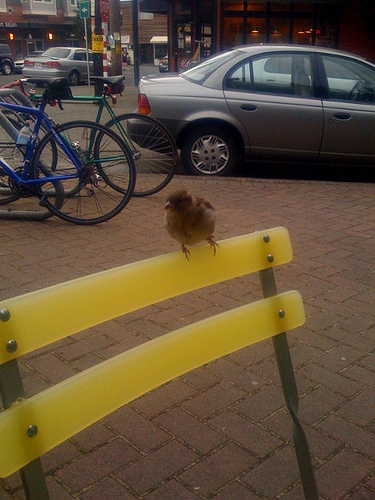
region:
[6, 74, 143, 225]
bright blue parked on sidewalk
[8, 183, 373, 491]
red brick sidewalk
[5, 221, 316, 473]
yellow slats of chair on sidewalk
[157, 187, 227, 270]
small brown bird perched on chair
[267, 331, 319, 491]
black iron twisted back of chair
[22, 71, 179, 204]
bright green bike parked on sidewalk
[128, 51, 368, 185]
silver car parked on street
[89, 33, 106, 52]
yellow on black pole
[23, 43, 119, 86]
silver car parked on street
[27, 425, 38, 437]
silver bolt in yellow chair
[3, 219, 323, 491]
yellow chair with bird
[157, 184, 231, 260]
small brown bird sitting on yellow chair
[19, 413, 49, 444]
silver screw in yellow chair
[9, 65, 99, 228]
blue collapsing bike parked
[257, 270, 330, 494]
twisted black metal back of chair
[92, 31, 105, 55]
yellow sign on black pole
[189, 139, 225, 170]
silver hubcap on black tire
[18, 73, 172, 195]
green bike parked on sidewalk next to car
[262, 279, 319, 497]
the rail is twisted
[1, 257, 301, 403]
the slats are yellow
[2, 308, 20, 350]
screws in the slat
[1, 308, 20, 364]
the screws are silver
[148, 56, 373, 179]
the car is parked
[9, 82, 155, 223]
bikes on the sidewalk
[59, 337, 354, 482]
the sidewalk is brick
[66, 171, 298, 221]
the brick is red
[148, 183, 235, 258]
bird on the chair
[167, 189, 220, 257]
the bird is brown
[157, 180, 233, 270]
Bird on a bench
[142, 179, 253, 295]
Brown colored bird on the bench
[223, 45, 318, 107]
Window of a car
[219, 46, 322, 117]
Window of a silver car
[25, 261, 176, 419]
Bench has a yellow top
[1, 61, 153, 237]
Two bicycles together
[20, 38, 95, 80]
Car in the background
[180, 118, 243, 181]
Tire of a car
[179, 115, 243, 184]
Back tire of a car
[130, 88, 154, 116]
Tail light of a car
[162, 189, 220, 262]
Bird perched on a yellow strip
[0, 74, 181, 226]
Two bicycles parked at the bike rack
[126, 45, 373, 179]
SIlver car parked at the curb